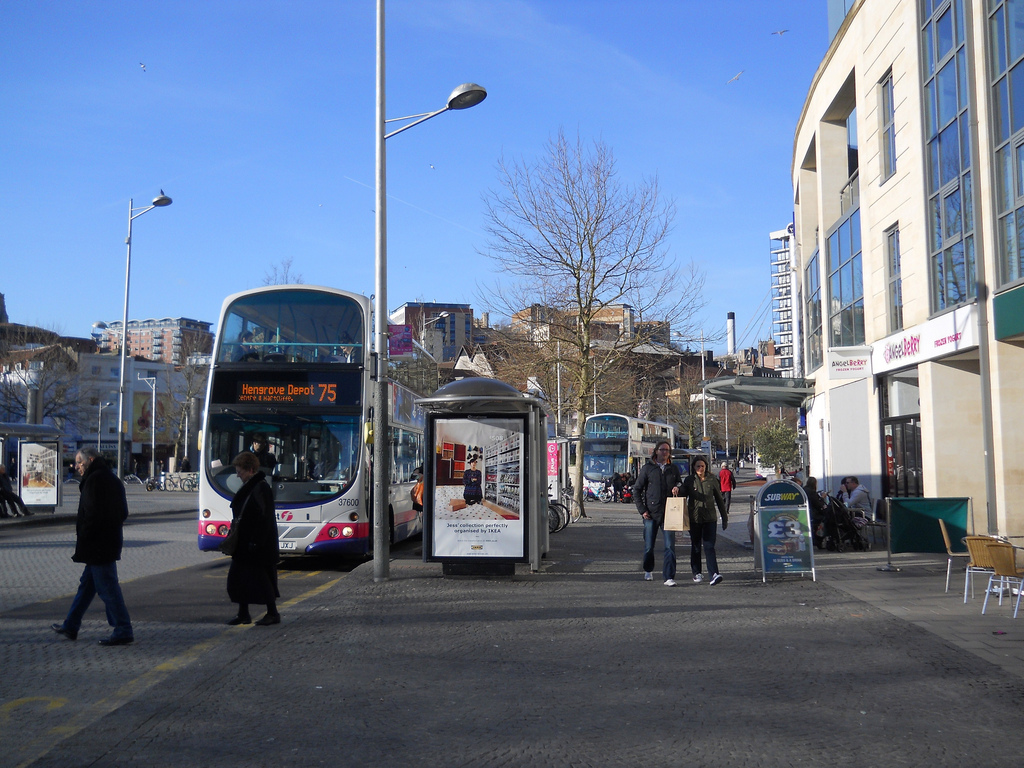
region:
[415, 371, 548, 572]
bus stop on sidewalk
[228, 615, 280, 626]
the shoes are black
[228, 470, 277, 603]
the coat is black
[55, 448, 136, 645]
a man is walking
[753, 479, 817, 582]
sign on the pavement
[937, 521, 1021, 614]
chairs on the ground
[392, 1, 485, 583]
street light on sidewalk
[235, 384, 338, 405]
the text is orange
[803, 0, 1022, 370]
windows on the building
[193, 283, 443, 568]
a double decker public service bus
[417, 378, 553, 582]
a public transportation shelter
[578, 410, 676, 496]
a double decker public service bus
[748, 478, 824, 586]
a portable business promotional sign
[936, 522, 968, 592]
a brown patio chair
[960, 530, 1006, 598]
a brown patio chair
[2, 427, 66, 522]
a public transportation shelter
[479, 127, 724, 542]
a large bare leafed tree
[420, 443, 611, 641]
a view of board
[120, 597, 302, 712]
a view of lines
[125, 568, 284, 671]
lines in the road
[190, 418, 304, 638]
a person in road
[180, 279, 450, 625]
a bus in the road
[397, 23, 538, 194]
a light on top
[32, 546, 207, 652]
legs of the perosn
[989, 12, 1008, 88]
glass window on building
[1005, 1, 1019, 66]
glass window on building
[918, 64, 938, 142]
glass window on building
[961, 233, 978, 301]
glass window on building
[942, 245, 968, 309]
glass window on building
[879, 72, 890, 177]
glass window on building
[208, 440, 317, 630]
A person wearing a long black coat crossing the street.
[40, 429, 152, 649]
A person wearing a short black coat crossing the street.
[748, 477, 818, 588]
A business sign on the ground in front of the building.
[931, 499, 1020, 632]
Chairs outside in front of the building.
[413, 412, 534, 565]
A poster ad on the street.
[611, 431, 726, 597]
Two people walking down the street.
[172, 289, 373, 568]
The front of the bus is white, red, and blue.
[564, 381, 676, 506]
A bus is parked on the side of the road.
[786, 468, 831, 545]
A person is sitting down in front of the building.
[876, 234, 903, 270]
A window on a building.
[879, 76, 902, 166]
A window on a building.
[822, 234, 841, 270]
A window on a building.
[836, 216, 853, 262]
A window on a building.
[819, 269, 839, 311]
A window on a building.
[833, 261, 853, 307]
A window on a building.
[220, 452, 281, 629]
lady is walking across the street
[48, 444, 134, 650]
person is wearing black jacket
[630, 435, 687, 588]
man is holding a bag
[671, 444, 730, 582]
lady is walking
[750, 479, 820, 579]
sign is beside lady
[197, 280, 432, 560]
bus is in the road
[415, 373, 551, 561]
sign is to the right of bus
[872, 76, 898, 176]
A window on a building.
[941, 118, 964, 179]
A window on a building.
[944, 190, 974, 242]
A window on a building.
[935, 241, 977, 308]
A window on a building.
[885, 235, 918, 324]
A window on a building.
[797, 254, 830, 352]
A window on a building.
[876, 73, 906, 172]
A window on a building.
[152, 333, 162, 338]
A window on a building.